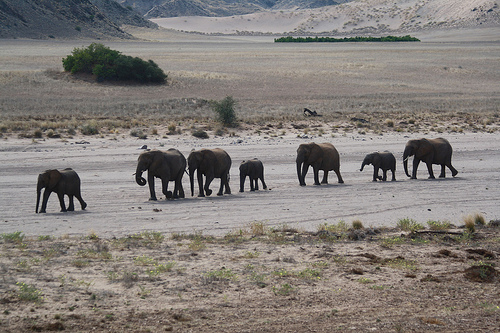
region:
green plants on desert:
[58, 31, 179, 108]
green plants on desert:
[30, 2, 207, 102]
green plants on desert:
[37, 45, 161, 89]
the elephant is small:
[356, 142, 396, 182]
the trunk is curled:
[131, 175, 150, 186]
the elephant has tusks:
[401, 149, 412, 165]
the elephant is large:
[287, 137, 347, 189]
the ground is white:
[187, 206, 301, 222]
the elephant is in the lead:
[24, 163, 95, 220]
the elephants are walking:
[15, 135, 464, 216]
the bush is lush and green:
[60, 36, 172, 90]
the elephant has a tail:
[179, 165, 190, 179]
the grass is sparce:
[73, 231, 332, 287]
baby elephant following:
[362, 149, 396, 181]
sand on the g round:
[123, 191, 455, 231]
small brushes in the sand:
[28, 46, 186, 90]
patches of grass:
[371, 218, 444, 240]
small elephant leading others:
[24, 178, 99, 205]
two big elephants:
[136, 151, 237, 205]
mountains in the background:
[170, 0, 496, 37]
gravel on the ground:
[189, 300, 473, 323]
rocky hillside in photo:
[1, 2, 174, 27]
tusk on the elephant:
[401, 150, 411, 166]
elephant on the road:
[20, 159, 103, 234]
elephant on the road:
[129, 141, 194, 206]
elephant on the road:
[180, 141, 237, 202]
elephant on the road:
[235, 150, 266, 196]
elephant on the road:
[285, 140, 345, 185]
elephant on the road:
[355, 143, 408, 185]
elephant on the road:
[399, 136, 462, 183]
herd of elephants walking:
[18, 118, 479, 241]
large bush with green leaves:
[56, 41, 167, 93]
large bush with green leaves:
[265, 28, 422, 47]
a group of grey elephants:
[29, 136, 460, 216]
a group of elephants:
[24, 137, 459, 214]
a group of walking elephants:
[33, 137, 460, 213]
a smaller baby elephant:
[237, 156, 267, 193]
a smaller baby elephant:
[356, 151, 396, 183]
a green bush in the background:
[63, 40, 170, 90]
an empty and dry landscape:
[0, 0, 496, 331]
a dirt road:
[0, 130, 499, 236]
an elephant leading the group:
[33, 165, 90, 218]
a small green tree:
[208, 91, 240, 133]